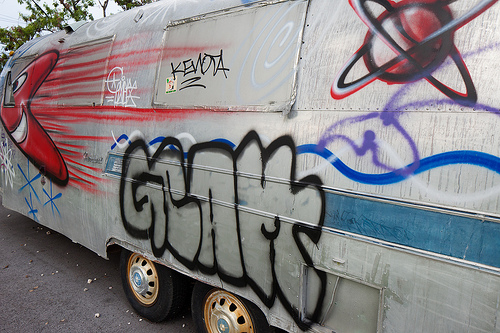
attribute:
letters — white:
[95, 56, 145, 101]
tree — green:
[1, 1, 151, 69]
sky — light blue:
[4, 0, 122, 48]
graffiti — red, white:
[4, 43, 78, 187]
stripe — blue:
[304, 188, 499, 265]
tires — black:
[115, 241, 261, 330]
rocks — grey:
[76, 251, 116, 329]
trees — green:
[1, 1, 124, 60]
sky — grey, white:
[2, 0, 119, 59]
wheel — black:
[111, 247, 188, 331]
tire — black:
[179, 275, 258, 331]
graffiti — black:
[113, 129, 326, 331]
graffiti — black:
[166, 48, 236, 88]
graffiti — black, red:
[326, 0, 496, 102]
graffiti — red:
[1, 48, 74, 179]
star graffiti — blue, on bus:
[8, 160, 74, 220]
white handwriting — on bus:
[104, 65, 141, 108]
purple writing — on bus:
[313, 85, 438, 165]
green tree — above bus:
[2, 1, 56, 32]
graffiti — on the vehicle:
[14, 33, 468, 329]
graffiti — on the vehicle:
[9, 41, 481, 240]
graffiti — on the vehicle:
[93, 47, 357, 331]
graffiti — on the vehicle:
[0, 48, 99, 229]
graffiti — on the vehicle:
[83, 45, 403, 278]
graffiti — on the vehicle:
[109, 51, 390, 276]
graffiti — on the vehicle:
[31, 46, 447, 316]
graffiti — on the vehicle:
[8, 50, 159, 226]